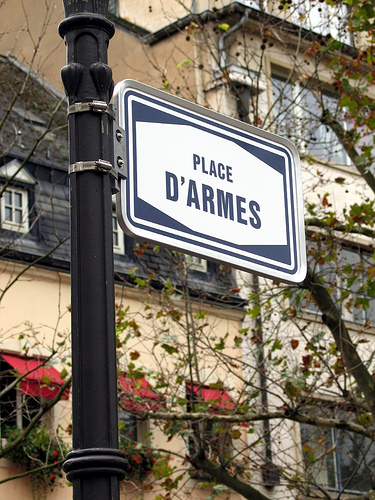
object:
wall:
[2, 258, 250, 498]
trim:
[60, 443, 133, 488]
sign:
[111, 80, 306, 283]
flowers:
[290, 340, 299, 350]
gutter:
[231, 82, 281, 492]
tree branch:
[144, 285, 374, 370]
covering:
[0, 350, 70, 400]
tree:
[0, 1, 375, 500]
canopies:
[0, 348, 245, 418]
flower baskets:
[21, 440, 162, 488]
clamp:
[58, 89, 127, 184]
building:
[217, 2, 373, 500]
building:
[1, 1, 233, 497]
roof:
[0, 53, 250, 312]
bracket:
[65, 99, 113, 117]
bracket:
[68, 159, 115, 174]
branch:
[183, 446, 270, 500]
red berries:
[46, 461, 56, 479]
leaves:
[13, 427, 47, 460]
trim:
[119, 73, 310, 156]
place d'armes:
[164, 152, 262, 230]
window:
[300, 227, 375, 329]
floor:
[253, 191, 364, 330]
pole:
[58, 0, 127, 500]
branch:
[141, 401, 282, 427]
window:
[0, 376, 43, 442]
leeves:
[359, 210, 371, 232]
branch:
[279, 402, 349, 433]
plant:
[308, 267, 372, 387]